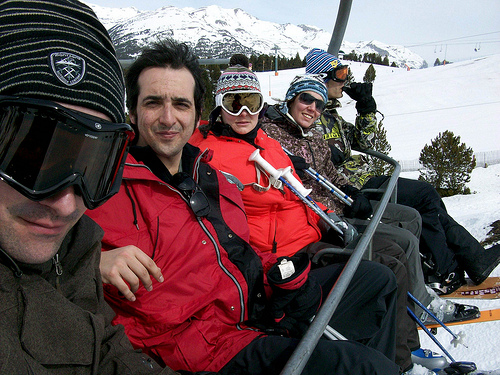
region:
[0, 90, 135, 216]
Black goggles on man's face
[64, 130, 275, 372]
Red jacket man is wearing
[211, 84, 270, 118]
White goggles on person's face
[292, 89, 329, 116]
Black sunglasses on person's face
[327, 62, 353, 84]
Black and orange goggles on person's face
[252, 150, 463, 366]
White and blue ski poles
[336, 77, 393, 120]
Black gloves person is wearing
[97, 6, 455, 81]
Snow capped mountains in distance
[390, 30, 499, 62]
Ski lift in distance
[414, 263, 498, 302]
Pair of brown and red skis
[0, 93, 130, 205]
black protective eyewear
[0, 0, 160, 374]
a seated man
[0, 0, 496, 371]
a ski lift full of people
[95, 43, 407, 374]
a man seated on ski lift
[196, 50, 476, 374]
a woman seated on ski lift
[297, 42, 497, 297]
a man seated on ski lift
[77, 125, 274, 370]
a red winter jacket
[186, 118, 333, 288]
a red winter jacket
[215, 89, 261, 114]
white protective eyewear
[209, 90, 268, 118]
The white snow goggles the person has on.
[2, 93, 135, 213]
The all black snow goggles the person on the left is wearing.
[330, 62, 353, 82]
The snow goggles the person on the right is wearing.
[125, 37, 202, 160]
The man's head with snow goggles.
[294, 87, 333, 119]
The girl wearing sunglasses.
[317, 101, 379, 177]
The guy's green and black jacket.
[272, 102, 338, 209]
The girl's pink and brown jacket.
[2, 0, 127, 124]
The black and white stripe hat the guy is wearing.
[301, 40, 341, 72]
The blue and white striped hat the guy is wearing.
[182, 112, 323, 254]
The red coat the girl is wearing.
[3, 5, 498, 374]
People on a chair lift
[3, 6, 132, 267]
A man in a black hat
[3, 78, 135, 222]
A man wearing goggles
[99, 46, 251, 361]
a man in a red jacket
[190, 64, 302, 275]
A person in an orange jacket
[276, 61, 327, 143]
A woman wearing sunglasses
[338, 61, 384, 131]
A black glove on a hand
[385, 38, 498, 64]
Chair lifts in the distance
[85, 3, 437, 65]
Mountains in the distance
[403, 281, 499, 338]
Ski boot and skiis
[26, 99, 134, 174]
Black goggles on man's face.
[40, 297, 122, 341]
Person wearing dark coat.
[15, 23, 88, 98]
black and tan hat on man's head.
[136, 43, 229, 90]
Person has dark hair.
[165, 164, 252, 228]
Black sunglasses on man's shirt.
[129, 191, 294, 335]
Man wearing red and black coat.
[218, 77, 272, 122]
White goggles on person's face.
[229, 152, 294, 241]
Person wearing red coat.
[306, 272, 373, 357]
Person wearing black pants.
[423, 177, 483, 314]
Person wearing black pants.